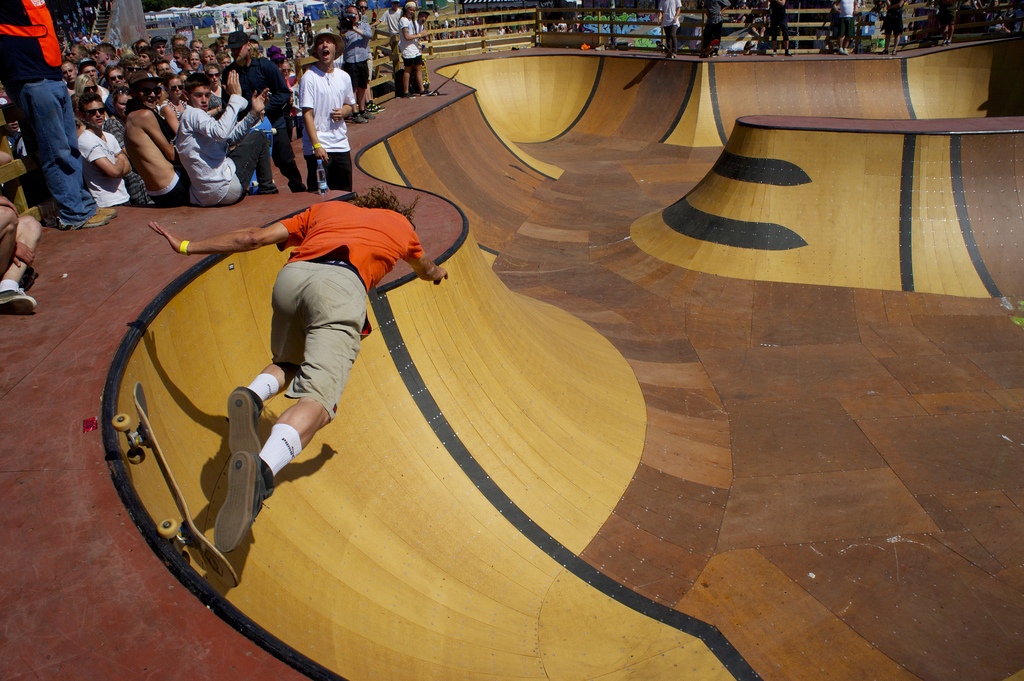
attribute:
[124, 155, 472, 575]
boy — skating, falling down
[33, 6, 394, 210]
kids — watching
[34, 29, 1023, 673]
ramp — wooden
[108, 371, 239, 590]
skateboard — ridden, wooden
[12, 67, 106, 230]
jeans — blue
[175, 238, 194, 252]
bracelet — yellow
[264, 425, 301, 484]
sock — white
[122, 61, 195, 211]
spectator — shirtless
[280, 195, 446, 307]
shirt — orange, orange colored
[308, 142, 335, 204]
water bottle — plastic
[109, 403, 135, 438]
wheel — yellow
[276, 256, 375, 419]
shorts — brown, tan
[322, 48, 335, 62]
mouth — opened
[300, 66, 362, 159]
shirt — white